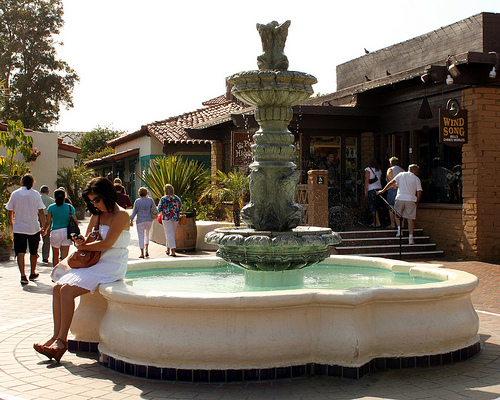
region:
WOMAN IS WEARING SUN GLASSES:
[90, 200, 101, 207]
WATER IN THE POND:
[342, 268, 362, 290]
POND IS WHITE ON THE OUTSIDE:
[198, 316, 243, 351]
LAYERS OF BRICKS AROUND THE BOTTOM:
[171, 372, 232, 380]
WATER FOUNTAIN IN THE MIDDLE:
[255, 35, 301, 271]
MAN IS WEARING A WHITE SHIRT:
[399, 181, 416, 197]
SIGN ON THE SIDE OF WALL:
[442, 106, 468, 145]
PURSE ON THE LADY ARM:
[367, 176, 382, 182]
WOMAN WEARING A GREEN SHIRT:
[47, 206, 67, 226]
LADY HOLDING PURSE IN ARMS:
[71, 253, 80, 267]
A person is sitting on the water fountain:
[16, 12, 496, 368]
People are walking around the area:
[6, 11, 486, 368]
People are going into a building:
[338, 116, 431, 251]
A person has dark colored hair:
[82, 173, 109, 213]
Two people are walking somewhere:
[126, 177, 183, 255]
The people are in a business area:
[6, 8, 494, 393]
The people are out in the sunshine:
[6, 5, 496, 387]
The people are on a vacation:
[8, 22, 490, 393]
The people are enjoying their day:
[5, 10, 485, 395]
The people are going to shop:
[5, 12, 486, 392]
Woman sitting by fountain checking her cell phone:
[34, 175, 132, 362]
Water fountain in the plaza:
[68, 14, 480, 374]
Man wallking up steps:
[377, 162, 424, 246]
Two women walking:
[131, 182, 182, 256]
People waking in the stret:
[4, 170, 178, 287]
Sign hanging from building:
[434, 95, 470, 148]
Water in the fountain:
[122, 265, 446, 294]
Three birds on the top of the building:
[359, 45, 397, 85]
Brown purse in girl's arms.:
[67, 218, 102, 270]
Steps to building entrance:
[333, 225, 443, 261]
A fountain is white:
[115, 173, 421, 382]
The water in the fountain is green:
[166, 264, 286, 306]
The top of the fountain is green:
[222, 15, 397, 302]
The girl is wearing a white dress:
[56, 210, 153, 307]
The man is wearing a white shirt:
[358, 147, 467, 259]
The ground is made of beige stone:
[21, 355, 74, 390]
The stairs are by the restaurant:
[318, 195, 497, 282]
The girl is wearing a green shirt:
[40, 188, 90, 235]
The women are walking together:
[131, 182, 253, 283]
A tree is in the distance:
[7, 20, 147, 137]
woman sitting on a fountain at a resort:
[32, 176, 130, 361]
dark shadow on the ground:
[38, 333, 498, 398]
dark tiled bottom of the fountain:
[66, 338, 478, 382]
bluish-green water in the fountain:
[125, 265, 441, 293]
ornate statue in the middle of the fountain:
[205, 19, 345, 270]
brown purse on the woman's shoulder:
[66, 211, 105, 268]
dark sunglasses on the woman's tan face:
[87, 193, 104, 208]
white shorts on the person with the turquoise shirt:
[48, 228, 73, 247]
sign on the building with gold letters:
[437, 104, 470, 146]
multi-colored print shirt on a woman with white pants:
[156, 195, 185, 222]